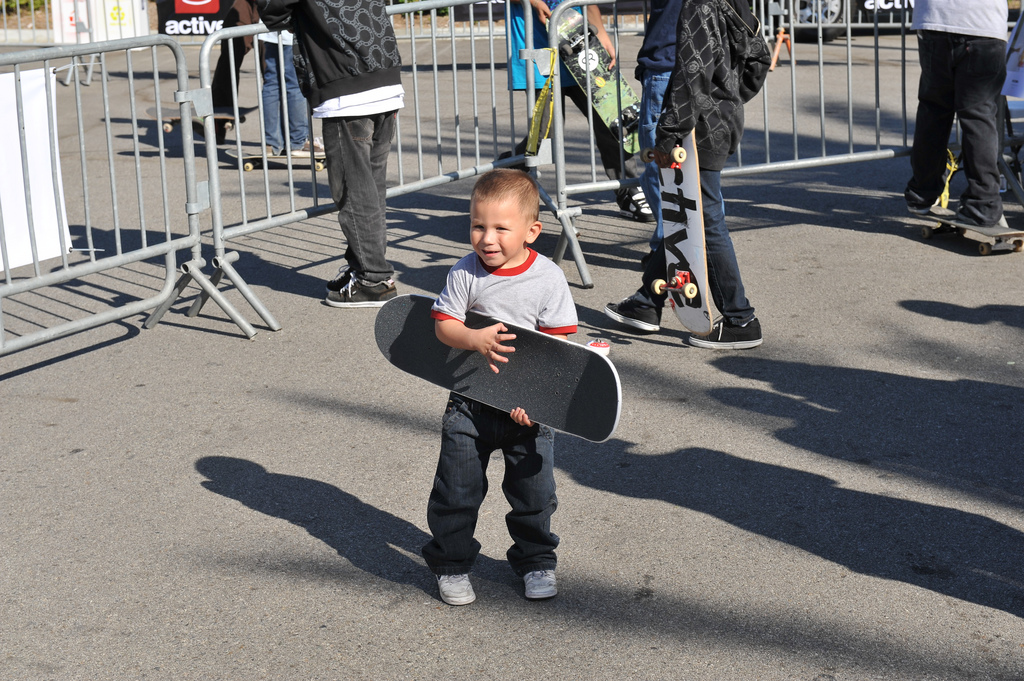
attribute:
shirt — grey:
[449, 234, 624, 395]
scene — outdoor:
[10, 5, 968, 652]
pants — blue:
[420, 368, 576, 582]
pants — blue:
[416, 394, 570, 578]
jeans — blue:
[414, 374, 566, 576]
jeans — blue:
[423, 379, 570, 581]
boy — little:
[403, 152, 594, 624]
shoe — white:
[425, 569, 486, 619]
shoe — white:
[511, 571, 566, 613]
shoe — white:
[431, 567, 483, 624]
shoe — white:
[518, 562, 568, 615]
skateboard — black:
[356, 290, 635, 465]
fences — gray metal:
[24, 52, 303, 402]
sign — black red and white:
[119, 8, 260, 84]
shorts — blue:
[433, 371, 516, 488]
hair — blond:
[463, 157, 550, 207]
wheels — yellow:
[396, 278, 634, 402]